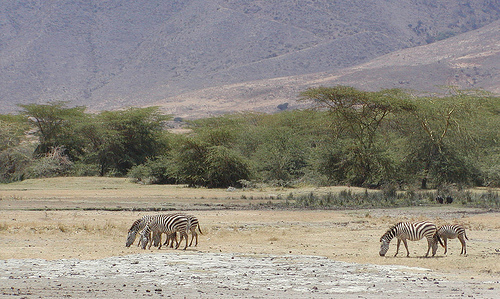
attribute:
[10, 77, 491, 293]
field — dry, brown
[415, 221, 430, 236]
stripes — white, black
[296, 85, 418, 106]
foliage — green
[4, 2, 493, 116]
mountains — distant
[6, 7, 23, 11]
hills — distant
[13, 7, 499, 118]
hills — barren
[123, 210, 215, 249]
zebras — grazing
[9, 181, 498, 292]
field — large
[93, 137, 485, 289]
zebras — group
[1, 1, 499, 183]
mountains — behind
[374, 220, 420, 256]
zebra — eating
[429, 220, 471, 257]
zebra — facing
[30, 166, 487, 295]
grass — dry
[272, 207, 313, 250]
grass — dry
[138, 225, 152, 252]
head — down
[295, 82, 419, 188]
tree — green, tall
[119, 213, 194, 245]
zebra — grazing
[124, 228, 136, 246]
head — down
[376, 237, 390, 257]
head — down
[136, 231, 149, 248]
head — down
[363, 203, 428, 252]
zebras — eating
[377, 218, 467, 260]
zebras — eating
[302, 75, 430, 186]
tree — tall, green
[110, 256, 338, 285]
pebbles — little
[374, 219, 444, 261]
zebra — black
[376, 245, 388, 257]
muzzle — black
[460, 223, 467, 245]
zebra tail — long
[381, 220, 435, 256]
zebra — two groups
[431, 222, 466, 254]
zebra — two groups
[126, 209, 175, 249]
zebra — two groups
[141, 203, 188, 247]
zebra — two groups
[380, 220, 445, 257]
zebra — grazing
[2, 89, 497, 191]
foliage — green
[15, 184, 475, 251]
vegetation — dried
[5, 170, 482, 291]
field — open